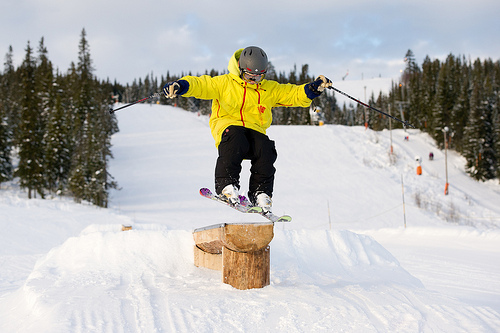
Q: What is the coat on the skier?
A: Yellow.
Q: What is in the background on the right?
A: Ski lift.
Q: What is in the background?
A: Pine trees.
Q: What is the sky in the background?
A: Partly cloudy.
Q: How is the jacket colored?
A: Yellow with red accents.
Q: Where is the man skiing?
A: Down a large slope.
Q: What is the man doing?
A: Jumping.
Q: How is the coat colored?
A: Yellow.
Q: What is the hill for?
A: Skiing.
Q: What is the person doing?
A: Skiing.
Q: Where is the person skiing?
A: Snow covered mountain.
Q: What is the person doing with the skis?
A: Jumping.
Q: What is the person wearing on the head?
A: Helmet.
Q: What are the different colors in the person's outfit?
A: Yellow, red and black.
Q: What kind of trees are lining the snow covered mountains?
A: Pine trees.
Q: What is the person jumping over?
A: Two tree stumps.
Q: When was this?
A: Daytime.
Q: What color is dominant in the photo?
A: White.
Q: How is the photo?
A: Clear.